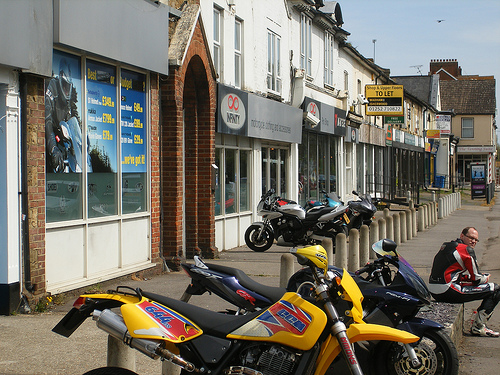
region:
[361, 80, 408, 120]
A yellow and black real-estate sign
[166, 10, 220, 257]
A brick doorway with a circular arch and pointed roof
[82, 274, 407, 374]
A yellow and red motorcycle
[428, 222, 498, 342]
A man in colorful leather cycling gear sitting on a curb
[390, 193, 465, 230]
A row of cement sidewalk barriers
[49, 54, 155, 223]
A storefront window with advertising posters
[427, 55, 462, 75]
A wide brick chimney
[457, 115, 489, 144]
A brown wall and two paned window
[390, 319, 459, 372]
A black motorcycle tire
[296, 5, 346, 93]
A pair of tall second story windows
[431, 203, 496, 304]
man sitting on the pavement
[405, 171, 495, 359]
man sitting on the pavement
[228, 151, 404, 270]
the motorbikes are parked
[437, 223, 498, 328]
the man is seated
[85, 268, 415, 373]
the bike is yellow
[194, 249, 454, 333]
the bike is blue in color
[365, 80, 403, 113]
the sign says to let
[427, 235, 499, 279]
the jacket is black and red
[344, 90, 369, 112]
camera is on the wall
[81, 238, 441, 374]
the bikes are two in number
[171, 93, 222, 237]
the wall is made of bricks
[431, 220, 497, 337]
the man has glasses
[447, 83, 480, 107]
the roof is grey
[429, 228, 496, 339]
a man sitting down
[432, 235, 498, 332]
a man in a red and black shirt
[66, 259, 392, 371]
a yellow motorcycle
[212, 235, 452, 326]
a black motorcycle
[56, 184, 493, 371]
parked motorcycles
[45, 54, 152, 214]
windows of the building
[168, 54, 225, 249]
a brick archway in the building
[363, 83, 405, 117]
a yellow sign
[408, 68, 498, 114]
the roof of the building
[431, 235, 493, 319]
a man sitting on the curb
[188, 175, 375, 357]
motorbike parking area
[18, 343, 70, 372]
the floor is grey in color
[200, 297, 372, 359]
the motorbike is yellow in color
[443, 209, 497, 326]
man seated beside a motorbike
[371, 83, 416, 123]
words written on a yellow board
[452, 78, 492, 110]
the roof is black brown in color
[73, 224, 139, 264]
the doors are metallic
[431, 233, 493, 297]
the outfit is black white and re in color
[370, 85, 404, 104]
the words are ritten in black color